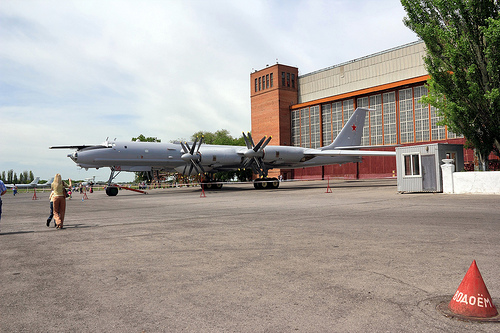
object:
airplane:
[47, 106, 423, 199]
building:
[243, 26, 500, 182]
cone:
[446, 256, 500, 320]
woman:
[48, 174, 68, 230]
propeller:
[238, 130, 274, 177]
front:
[63, 134, 155, 175]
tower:
[246, 62, 303, 183]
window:
[290, 108, 303, 147]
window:
[382, 89, 399, 145]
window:
[413, 84, 432, 143]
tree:
[399, 0, 499, 174]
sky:
[0, 0, 441, 183]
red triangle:
[199, 190, 207, 198]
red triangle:
[325, 187, 333, 193]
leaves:
[442, 36, 471, 60]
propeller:
[177, 135, 209, 179]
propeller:
[66, 150, 79, 163]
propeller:
[139, 171, 156, 183]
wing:
[304, 146, 400, 162]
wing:
[44, 141, 111, 155]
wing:
[368, 94, 384, 145]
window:
[332, 101, 343, 144]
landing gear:
[104, 170, 119, 197]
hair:
[53, 173, 63, 189]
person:
[49, 171, 73, 231]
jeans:
[46, 201, 58, 229]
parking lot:
[0, 103, 417, 199]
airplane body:
[64, 140, 362, 176]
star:
[350, 123, 358, 132]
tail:
[318, 107, 376, 151]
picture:
[0, 0, 500, 333]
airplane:
[0, 176, 60, 189]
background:
[0, 132, 252, 201]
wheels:
[253, 178, 270, 190]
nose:
[65, 143, 105, 170]